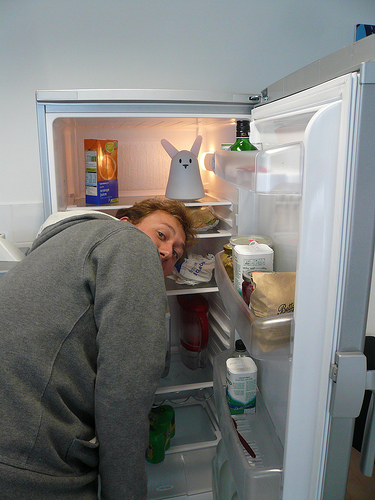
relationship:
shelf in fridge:
[72, 186, 234, 245] [34, 35, 375, 500]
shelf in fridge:
[62, 186, 234, 297] [34, 35, 375, 500]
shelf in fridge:
[138, 366, 233, 467] [34, 35, 375, 500]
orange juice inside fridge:
[80, 136, 127, 207] [34, 35, 375, 500]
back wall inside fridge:
[68, 124, 210, 389] [34, 35, 375, 500]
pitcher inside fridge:
[179, 297, 203, 356] [34, 35, 375, 500]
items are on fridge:
[88, 140, 289, 391] [34, 35, 375, 500]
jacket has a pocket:
[0, 215, 171, 500] [66, 433, 109, 463]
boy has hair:
[0, 197, 203, 500] [133, 199, 193, 228]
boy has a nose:
[0, 197, 203, 500] [156, 246, 173, 260]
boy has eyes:
[0, 197, 203, 500] [148, 228, 186, 262]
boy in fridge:
[0, 197, 203, 500] [34, 35, 375, 500]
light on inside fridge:
[197, 141, 220, 185] [34, 35, 375, 500]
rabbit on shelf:
[158, 136, 207, 206] [72, 186, 234, 245]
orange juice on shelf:
[80, 136, 127, 207] [72, 186, 234, 245]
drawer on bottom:
[98, 408, 251, 499] [126, 478, 216, 499]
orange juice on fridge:
[80, 136, 127, 207] [34, 70, 355, 499]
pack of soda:
[123, 409, 187, 462] [143, 401, 178, 469]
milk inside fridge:
[220, 351, 263, 422] [34, 70, 355, 499]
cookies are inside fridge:
[167, 248, 222, 287] [34, 70, 355, 499]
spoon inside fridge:
[173, 277, 200, 289] [34, 70, 355, 499]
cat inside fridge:
[162, 131, 207, 204] [34, 70, 355, 499]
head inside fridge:
[119, 197, 198, 279] [34, 70, 355, 499]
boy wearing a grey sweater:
[0, 197, 203, 500] [0, 215, 171, 500]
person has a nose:
[0, 215, 171, 500] [156, 246, 173, 260]